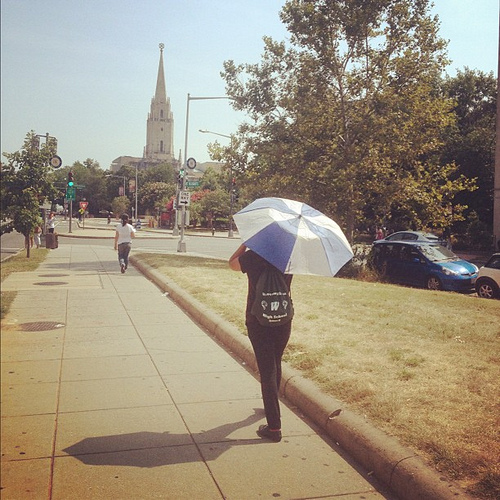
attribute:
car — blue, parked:
[362, 231, 480, 302]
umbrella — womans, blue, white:
[230, 192, 360, 283]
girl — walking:
[226, 225, 304, 446]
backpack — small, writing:
[247, 267, 296, 337]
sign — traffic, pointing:
[175, 188, 196, 212]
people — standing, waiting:
[110, 211, 138, 277]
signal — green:
[67, 166, 75, 195]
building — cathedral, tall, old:
[108, 37, 248, 211]